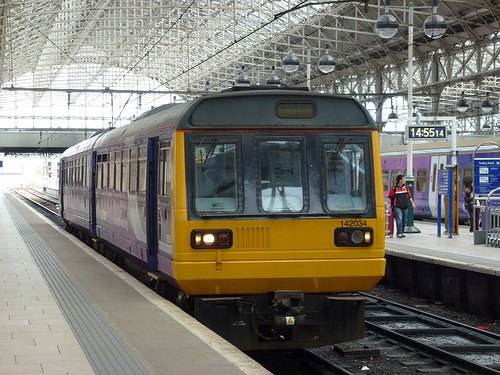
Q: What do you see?
A: Back of the train.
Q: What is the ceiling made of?
A: Metal.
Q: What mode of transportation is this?
A: Commuter train.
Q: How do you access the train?
A: The platform.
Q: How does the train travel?
A: On the tracks.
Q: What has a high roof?
A: The train station.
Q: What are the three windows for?
A: The windshield.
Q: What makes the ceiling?
A: The metal bars.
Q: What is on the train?
A: The windshield.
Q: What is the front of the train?
A: Yellow.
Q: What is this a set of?
A: Train tracks.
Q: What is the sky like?
A: Bright and gray.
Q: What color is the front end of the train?
A: Yellow.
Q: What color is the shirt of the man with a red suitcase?
A: Red, white and black.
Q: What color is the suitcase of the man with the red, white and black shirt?
A: Red.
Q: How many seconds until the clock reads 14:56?
A: 46.